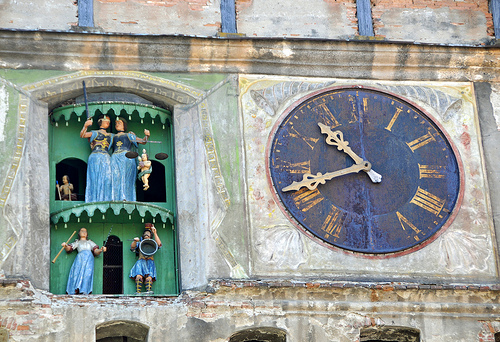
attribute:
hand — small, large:
[280, 165, 374, 200]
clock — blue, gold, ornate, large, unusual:
[263, 89, 455, 250]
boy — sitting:
[50, 178, 85, 206]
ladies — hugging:
[83, 124, 140, 202]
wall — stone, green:
[253, 269, 356, 306]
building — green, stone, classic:
[72, 34, 461, 335]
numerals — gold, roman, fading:
[327, 105, 412, 135]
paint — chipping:
[207, 18, 265, 91]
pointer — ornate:
[317, 110, 402, 165]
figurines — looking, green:
[29, 74, 169, 305]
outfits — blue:
[88, 170, 145, 184]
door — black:
[63, 159, 76, 189]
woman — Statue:
[59, 225, 98, 294]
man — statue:
[110, 141, 134, 207]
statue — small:
[117, 259, 152, 288]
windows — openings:
[91, 236, 148, 318]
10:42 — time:
[252, 109, 372, 187]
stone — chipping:
[211, 16, 266, 76]